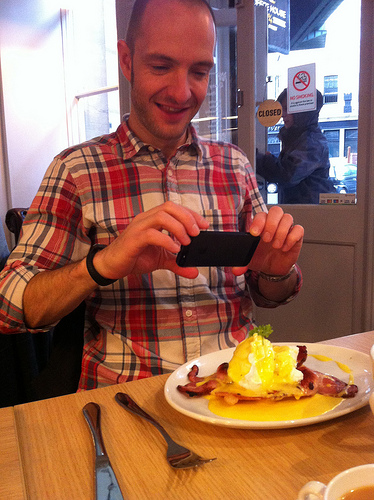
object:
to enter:
[211, 0, 345, 214]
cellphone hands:
[112, 200, 304, 279]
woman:
[255, 88, 337, 204]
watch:
[259, 263, 297, 281]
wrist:
[259, 263, 298, 282]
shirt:
[0, 113, 302, 394]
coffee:
[299, 464, 373, 500]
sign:
[257, 98, 282, 127]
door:
[237, 0, 374, 344]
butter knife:
[82, 402, 125, 500]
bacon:
[175, 345, 358, 398]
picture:
[0, 0, 374, 500]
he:
[0, 0, 303, 393]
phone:
[176, 230, 262, 267]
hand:
[233, 205, 305, 277]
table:
[0, 329, 374, 499]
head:
[116, 1, 217, 139]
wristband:
[86, 243, 118, 286]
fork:
[114, 392, 217, 471]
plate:
[164, 342, 374, 429]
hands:
[114, 201, 209, 279]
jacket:
[255, 87, 335, 204]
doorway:
[228, 3, 370, 345]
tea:
[344, 487, 374, 499]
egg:
[196, 332, 353, 422]